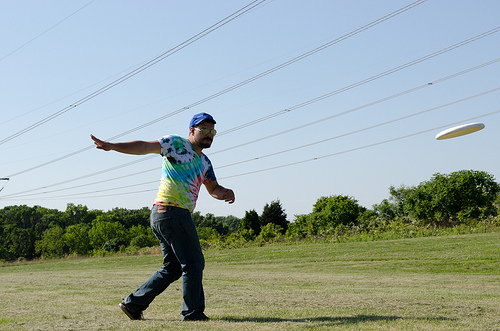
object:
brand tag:
[157, 205, 167, 214]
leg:
[156, 217, 206, 315]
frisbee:
[435, 122, 486, 141]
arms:
[202, 157, 222, 196]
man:
[88, 111, 234, 321]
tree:
[0, 204, 71, 261]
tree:
[35, 201, 89, 258]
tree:
[87, 206, 130, 255]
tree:
[121, 205, 161, 254]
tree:
[193, 206, 241, 251]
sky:
[0, 0, 499, 209]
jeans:
[124, 204, 207, 314]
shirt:
[151, 134, 217, 211]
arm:
[114, 134, 180, 155]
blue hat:
[188, 112, 217, 129]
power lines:
[0, 0, 499, 197]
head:
[188, 112, 217, 148]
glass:
[193, 124, 216, 136]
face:
[194, 121, 216, 147]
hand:
[89, 134, 111, 152]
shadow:
[206, 314, 458, 330]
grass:
[0, 229, 498, 328]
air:
[0, 0, 499, 222]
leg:
[133, 227, 182, 302]